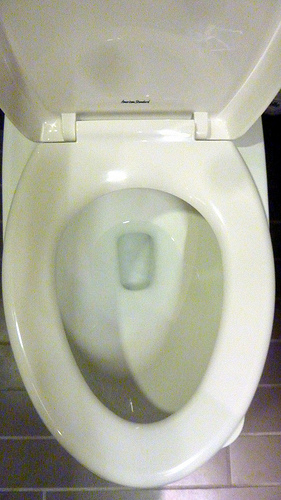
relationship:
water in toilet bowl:
[50, 184, 224, 427] [54, 191, 221, 426]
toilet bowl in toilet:
[54, 191, 221, 426] [5, 7, 276, 484]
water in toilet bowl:
[123, 333, 185, 380] [54, 191, 221, 426]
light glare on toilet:
[102, 167, 133, 186] [5, 7, 276, 484]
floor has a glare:
[1, 111, 279, 498] [158, 483, 203, 499]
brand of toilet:
[119, 95, 153, 109] [5, 7, 276, 484]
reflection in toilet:
[150, 208, 190, 246] [5, 7, 276, 484]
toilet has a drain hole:
[5, 7, 276, 484] [113, 231, 158, 290]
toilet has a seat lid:
[5, 7, 276, 484] [0, 2, 280, 143]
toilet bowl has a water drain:
[54, 191, 221, 426] [113, 231, 158, 290]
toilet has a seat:
[5, 7, 276, 484] [5, 120, 274, 491]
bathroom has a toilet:
[5, 7, 276, 484] [5, 7, 276, 484]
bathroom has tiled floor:
[5, 7, 276, 484] [246, 414, 280, 500]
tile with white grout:
[0, 424, 47, 499] [1, 485, 121, 493]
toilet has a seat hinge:
[5, 7, 276, 484] [193, 111, 211, 139]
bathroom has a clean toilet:
[5, 7, 276, 484] [5, 7, 276, 484]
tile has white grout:
[0, 424, 47, 499] [1, 485, 121, 493]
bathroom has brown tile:
[5, 7, 276, 484] [246, 414, 280, 500]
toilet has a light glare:
[5, 7, 276, 484] [155, 126, 188, 145]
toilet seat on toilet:
[5, 120, 274, 491] [5, 7, 276, 484]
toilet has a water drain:
[5, 7, 276, 484] [113, 231, 158, 290]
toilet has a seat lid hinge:
[5, 7, 276, 484] [193, 111, 211, 139]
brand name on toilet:
[119, 95, 153, 109] [5, 7, 276, 484]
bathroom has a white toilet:
[5, 7, 276, 484] [5, 7, 276, 484]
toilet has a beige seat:
[5, 7, 276, 484] [5, 120, 274, 491]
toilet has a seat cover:
[5, 7, 276, 484] [0, 2, 280, 143]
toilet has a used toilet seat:
[5, 7, 276, 484] [5, 120, 274, 491]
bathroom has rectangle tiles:
[5, 7, 276, 484] [219, 444, 279, 500]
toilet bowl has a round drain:
[54, 191, 221, 426] [113, 231, 158, 290]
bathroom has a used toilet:
[5, 7, 276, 484] [5, 7, 276, 484]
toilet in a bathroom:
[5, 7, 276, 484] [5, 7, 276, 484]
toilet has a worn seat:
[5, 7, 276, 484] [5, 120, 274, 491]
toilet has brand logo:
[5, 7, 276, 484] [119, 95, 153, 109]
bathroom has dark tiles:
[5, 7, 276, 484] [0, 424, 47, 499]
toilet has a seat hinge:
[56, 113, 79, 145] [193, 111, 211, 139]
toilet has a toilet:
[5, 7, 276, 484] [56, 113, 79, 145]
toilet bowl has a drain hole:
[54, 191, 221, 426] [113, 231, 158, 290]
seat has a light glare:
[5, 120, 274, 491] [155, 126, 188, 145]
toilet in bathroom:
[5, 7, 276, 484] [5, 7, 276, 484]